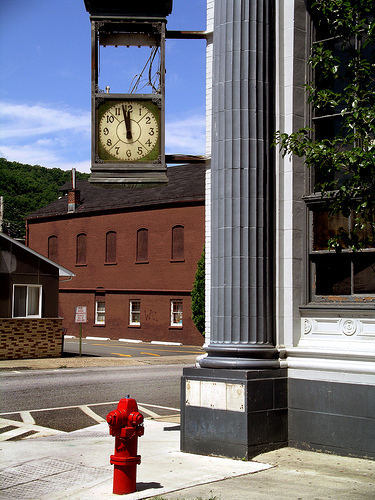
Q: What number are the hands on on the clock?
A: 12.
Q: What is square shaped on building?
A: Window.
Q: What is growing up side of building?
A: Green foliage.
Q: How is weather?
A: Blue sky with white clouds.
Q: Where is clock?
A: Hanging from building.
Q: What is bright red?
A: Fire hydrant.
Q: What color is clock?
A: Green and white.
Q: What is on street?
A: White paint.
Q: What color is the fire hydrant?
A: Red.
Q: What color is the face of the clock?
A: White.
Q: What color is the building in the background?
A: Brown.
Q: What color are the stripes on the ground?
A: White.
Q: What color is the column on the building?
A: Grey.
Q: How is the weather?
A: Sunny.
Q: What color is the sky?
A: Blue.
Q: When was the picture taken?
A: Daytime.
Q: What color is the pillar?
A: Black.